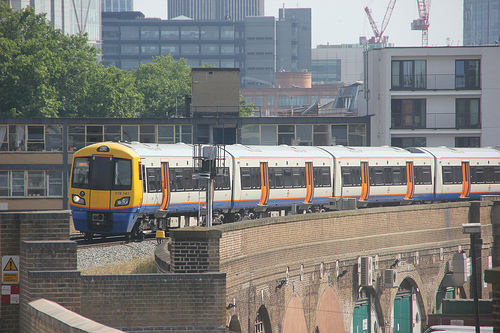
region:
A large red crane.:
[408, 0, 431, 44]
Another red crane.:
[361, 2, 397, 44]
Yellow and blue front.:
[68, 142, 143, 237]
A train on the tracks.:
[55, 138, 498, 250]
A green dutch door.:
[388, 289, 414, 331]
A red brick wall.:
[174, 239, 224, 331]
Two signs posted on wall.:
[0, 246, 27, 313]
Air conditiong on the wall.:
[380, 263, 400, 294]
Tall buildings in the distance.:
[105, 10, 350, 87]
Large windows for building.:
[392, 59, 484, 149]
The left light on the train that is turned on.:
[68, 196, 84, 204]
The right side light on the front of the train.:
[113, 194, 128, 205]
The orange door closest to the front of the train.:
[157, 160, 169, 214]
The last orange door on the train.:
[455, 157, 470, 196]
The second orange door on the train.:
[252, 160, 276, 212]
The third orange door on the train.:
[297, 157, 318, 200]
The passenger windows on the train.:
[143, 166, 498, 181]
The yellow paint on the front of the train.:
[68, 140, 142, 210]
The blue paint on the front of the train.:
[63, 200, 138, 235]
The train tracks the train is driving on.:
[56, 218, 134, 244]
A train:
[105, 69, 347, 240]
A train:
[146, 191, 319, 291]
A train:
[146, 125, 251, 238]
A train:
[164, 153, 279, 327]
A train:
[124, 126, 301, 284]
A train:
[85, 111, 197, 257]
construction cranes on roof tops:
[346, 0, 437, 63]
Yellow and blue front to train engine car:
[58, 142, 158, 242]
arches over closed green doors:
[346, 258, 477, 330]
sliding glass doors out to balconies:
[386, 52, 499, 142]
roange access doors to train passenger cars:
[360, 160, 470, 209]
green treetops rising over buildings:
[1, 2, 193, 116]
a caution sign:
[1, 248, 20, 296]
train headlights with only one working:
[63, 190, 145, 218]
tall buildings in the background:
[20, 1, 370, 93]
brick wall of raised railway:
[6, 214, 233, 316]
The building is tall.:
[358, 43, 499, 148]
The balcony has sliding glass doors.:
[385, 53, 429, 91]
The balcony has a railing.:
[390, 97, 433, 134]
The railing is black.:
[447, 55, 482, 91]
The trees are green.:
[1, 4, 189, 120]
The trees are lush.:
[0, 3, 190, 116]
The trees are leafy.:
[0, 0, 195, 120]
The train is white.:
[69, 137, 496, 233]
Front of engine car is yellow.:
[66, 137, 236, 242]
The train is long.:
[68, 137, 499, 247]